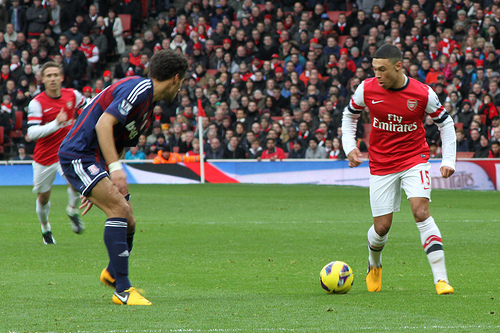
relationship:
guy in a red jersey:
[340, 44, 456, 294] [353, 75, 438, 170]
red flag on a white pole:
[192, 96, 209, 118] [192, 116, 213, 187]